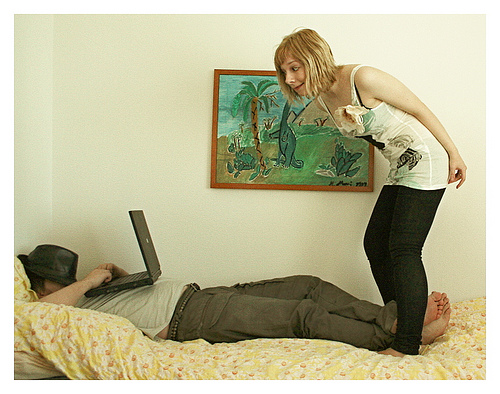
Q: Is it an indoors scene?
A: Yes, it is indoors.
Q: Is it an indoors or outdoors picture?
A: It is indoors.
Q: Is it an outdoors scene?
A: No, it is indoors.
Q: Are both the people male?
A: No, they are both male and female.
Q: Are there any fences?
A: No, there are no fences.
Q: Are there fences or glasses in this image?
A: No, there are no fences or glasses.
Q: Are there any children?
A: No, there are no children.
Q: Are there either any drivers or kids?
A: No, there are no kids or drivers.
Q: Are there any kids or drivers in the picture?
A: No, there are no kids or drivers.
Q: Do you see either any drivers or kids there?
A: No, there are no kids or drivers.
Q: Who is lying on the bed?
A: The man is lying on the bed.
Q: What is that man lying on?
A: The man is lying on the bed.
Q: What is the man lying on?
A: The man is lying on the bed.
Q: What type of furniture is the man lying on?
A: The man is lying on the bed.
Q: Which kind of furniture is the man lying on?
A: The man is lying on the bed.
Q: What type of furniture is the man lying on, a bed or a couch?
A: The man is lying on a bed.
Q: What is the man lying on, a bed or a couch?
A: The man is lying on a bed.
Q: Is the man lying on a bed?
A: Yes, the man is lying on a bed.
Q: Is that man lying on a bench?
A: No, the man is lying on a bed.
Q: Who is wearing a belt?
A: The man is wearing a belt.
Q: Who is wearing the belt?
A: The man is wearing a belt.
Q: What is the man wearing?
A: The man is wearing a belt.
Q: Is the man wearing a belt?
A: Yes, the man is wearing a belt.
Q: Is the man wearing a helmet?
A: No, the man is wearing a belt.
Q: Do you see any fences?
A: No, there are no fences.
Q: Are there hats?
A: Yes, there is a hat.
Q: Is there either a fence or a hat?
A: Yes, there is a hat.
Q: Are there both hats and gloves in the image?
A: No, there is a hat but no gloves.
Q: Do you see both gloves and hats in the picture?
A: No, there is a hat but no gloves.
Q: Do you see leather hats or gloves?
A: Yes, there is a leather hat.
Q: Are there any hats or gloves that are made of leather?
A: Yes, the hat is made of leather.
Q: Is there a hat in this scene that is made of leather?
A: Yes, there is a hat that is made of leather.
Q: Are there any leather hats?
A: Yes, there is a hat that is made of leather.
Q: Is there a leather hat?
A: Yes, there is a hat that is made of leather.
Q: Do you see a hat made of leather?
A: Yes, there is a hat that is made of leather.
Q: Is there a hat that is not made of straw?
A: Yes, there is a hat that is made of leather.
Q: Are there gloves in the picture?
A: No, there are no gloves.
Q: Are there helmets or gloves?
A: No, there are no gloves or helmets.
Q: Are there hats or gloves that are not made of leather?
A: No, there is a hat but it is made of leather.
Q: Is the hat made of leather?
A: Yes, the hat is made of leather.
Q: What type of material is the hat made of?
A: The hat is made of leather.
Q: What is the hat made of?
A: The hat is made of leather.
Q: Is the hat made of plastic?
A: No, the hat is made of leather.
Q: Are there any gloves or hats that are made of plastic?
A: No, there is a hat but it is made of leather.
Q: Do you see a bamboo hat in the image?
A: No, there is a hat but it is made of leather.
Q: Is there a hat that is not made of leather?
A: No, there is a hat but it is made of leather.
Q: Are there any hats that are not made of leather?
A: No, there is a hat but it is made of leather.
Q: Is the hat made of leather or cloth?
A: The hat is made of leather.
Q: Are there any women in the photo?
A: Yes, there is a woman.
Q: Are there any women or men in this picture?
A: Yes, there is a woman.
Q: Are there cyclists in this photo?
A: No, there are no cyclists.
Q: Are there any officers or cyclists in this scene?
A: No, there are no cyclists or officers.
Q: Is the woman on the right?
A: Yes, the woman is on the right of the image.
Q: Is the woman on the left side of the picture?
A: No, the woman is on the right of the image.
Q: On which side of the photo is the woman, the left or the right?
A: The woman is on the right of the image.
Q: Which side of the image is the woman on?
A: The woman is on the right of the image.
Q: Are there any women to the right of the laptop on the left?
A: Yes, there is a woman to the right of the laptop computer.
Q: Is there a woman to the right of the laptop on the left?
A: Yes, there is a woman to the right of the laptop computer.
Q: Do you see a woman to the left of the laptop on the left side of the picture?
A: No, the woman is to the right of the laptop computer.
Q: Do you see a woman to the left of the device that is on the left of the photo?
A: No, the woman is to the right of the laptop computer.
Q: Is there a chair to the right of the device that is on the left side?
A: No, there is a woman to the right of the laptop.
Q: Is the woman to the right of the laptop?
A: Yes, the woman is to the right of the laptop.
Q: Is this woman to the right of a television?
A: No, the woman is to the right of the laptop.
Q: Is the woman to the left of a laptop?
A: No, the woman is to the right of a laptop.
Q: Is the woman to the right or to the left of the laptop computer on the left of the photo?
A: The woman is to the right of the laptop computer.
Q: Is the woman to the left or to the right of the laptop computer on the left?
A: The woman is to the right of the laptop computer.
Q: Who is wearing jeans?
A: The woman is wearing jeans.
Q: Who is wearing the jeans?
A: The woman is wearing jeans.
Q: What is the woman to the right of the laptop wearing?
A: The woman is wearing jeans.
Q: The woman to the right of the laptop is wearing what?
A: The woman is wearing jeans.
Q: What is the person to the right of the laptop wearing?
A: The woman is wearing jeans.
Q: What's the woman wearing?
A: The woman is wearing jeans.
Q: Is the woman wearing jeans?
A: Yes, the woman is wearing jeans.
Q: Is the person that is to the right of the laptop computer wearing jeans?
A: Yes, the woman is wearing jeans.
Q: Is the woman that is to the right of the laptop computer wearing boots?
A: No, the woman is wearing jeans.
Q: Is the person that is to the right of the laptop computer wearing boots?
A: No, the woman is wearing jeans.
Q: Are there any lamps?
A: No, there are no lamps.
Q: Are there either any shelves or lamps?
A: No, there are no lamps or shelves.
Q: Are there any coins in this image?
A: No, there are no coins.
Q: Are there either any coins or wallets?
A: No, there are no coins or wallets.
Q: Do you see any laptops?
A: Yes, there is a laptop.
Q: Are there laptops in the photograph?
A: Yes, there is a laptop.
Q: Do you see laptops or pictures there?
A: Yes, there is a laptop.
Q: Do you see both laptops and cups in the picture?
A: No, there is a laptop but no cups.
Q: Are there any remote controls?
A: No, there are no remote controls.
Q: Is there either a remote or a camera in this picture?
A: No, there are no remote controls or cameras.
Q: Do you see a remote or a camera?
A: No, there are no remote controls or cameras.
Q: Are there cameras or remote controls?
A: No, there are no remote controls or cameras.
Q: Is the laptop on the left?
A: Yes, the laptop is on the left of the image.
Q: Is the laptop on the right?
A: No, the laptop is on the left of the image.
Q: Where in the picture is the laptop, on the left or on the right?
A: The laptop is on the left of the image.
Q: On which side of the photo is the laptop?
A: The laptop is on the left of the image.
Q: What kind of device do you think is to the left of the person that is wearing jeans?
A: The device is a laptop.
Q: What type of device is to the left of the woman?
A: The device is a laptop.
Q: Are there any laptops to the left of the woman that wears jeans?
A: Yes, there is a laptop to the left of the woman.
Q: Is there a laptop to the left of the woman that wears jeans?
A: Yes, there is a laptop to the left of the woman.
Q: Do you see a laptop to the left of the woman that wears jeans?
A: Yes, there is a laptop to the left of the woman.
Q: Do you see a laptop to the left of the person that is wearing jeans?
A: Yes, there is a laptop to the left of the woman.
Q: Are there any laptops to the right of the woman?
A: No, the laptop is to the left of the woman.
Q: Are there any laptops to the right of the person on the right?
A: No, the laptop is to the left of the woman.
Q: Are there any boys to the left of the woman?
A: No, there is a laptop to the left of the woman.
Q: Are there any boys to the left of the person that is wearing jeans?
A: No, there is a laptop to the left of the woman.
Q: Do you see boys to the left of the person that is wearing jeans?
A: No, there is a laptop to the left of the woman.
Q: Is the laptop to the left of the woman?
A: Yes, the laptop is to the left of the woman.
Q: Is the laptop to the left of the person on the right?
A: Yes, the laptop is to the left of the woman.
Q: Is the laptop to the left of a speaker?
A: No, the laptop is to the left of the woman.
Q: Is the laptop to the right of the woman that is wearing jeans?
A: No, the laptop is to the left of the woman.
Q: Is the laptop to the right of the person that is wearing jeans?
A: No, the laptop is to the left of the woman.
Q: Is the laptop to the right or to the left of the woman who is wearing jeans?
A: The laptop is to the left of the woman.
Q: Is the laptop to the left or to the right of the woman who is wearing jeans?
A: The laptop is to the left of the woman.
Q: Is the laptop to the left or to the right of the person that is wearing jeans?
A: The laptop is to the left of the woman.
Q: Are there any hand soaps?
A: No, there are no hand soaps.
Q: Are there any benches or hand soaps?
A: No, there are no hand soaps or benches.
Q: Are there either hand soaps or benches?
A: No, there are no hand soaps or benches.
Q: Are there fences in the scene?
A: No, there are no fences.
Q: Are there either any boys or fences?
A: No, there are no fences or boys.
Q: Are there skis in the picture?
A: No, there are no skis.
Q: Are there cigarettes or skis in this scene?
A: No, there are no skis or cigarettes.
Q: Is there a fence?
A: No, there are no fences.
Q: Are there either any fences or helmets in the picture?
A: No, there are no fences or helmets.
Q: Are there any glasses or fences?
A: No, there are no glasses or fences.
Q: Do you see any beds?
A: Yes, there is a bed.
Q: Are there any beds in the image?
A: Yes, there is a bed.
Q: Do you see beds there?
A: Yes, there is a bed.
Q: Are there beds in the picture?
A: Yes, there is a bed.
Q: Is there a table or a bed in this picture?
A: Yes, there is a bed.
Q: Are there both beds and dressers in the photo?
A: No, there is a bed but no dressers.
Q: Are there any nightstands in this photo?
A: No, there are no nightstands.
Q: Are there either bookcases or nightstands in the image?
A: No, there are no nightstands or bookcases.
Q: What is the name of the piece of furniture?
A: The piece of furniture is a bed.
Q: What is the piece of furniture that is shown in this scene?
A: The piece of furniture is a bed.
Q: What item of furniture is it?
A: The piece of furniture is a bed.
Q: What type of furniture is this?
A: That is a bed.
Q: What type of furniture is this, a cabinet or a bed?
A: That is a bed.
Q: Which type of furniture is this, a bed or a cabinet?
A: That is a bed.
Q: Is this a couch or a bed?
A: This is a bed.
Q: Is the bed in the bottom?
A: Yes, the bed is in the bottom of the image.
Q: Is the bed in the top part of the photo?
A: No, the bed is in the bottom of the image.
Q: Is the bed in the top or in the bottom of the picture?
A: The bed is in the bottom of the image.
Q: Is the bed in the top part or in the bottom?
A: The bed is in the bottom of the image.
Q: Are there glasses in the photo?
A: No, there are no glasses.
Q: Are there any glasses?
A: No, there are no glasses.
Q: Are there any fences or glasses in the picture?
A: No, there are no glasses or fences.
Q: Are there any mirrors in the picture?
A: No, there are no mirrors.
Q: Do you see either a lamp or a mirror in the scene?
A: No, there are no mirrors or lamps.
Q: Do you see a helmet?
A: No, there are no helmets.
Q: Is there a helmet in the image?
A: No, there are no helmets.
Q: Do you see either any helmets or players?
A: No, there are no helmets or players.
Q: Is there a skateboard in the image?
A: No, there are no skateboards.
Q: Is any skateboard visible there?
A: No, there are no skateboards.